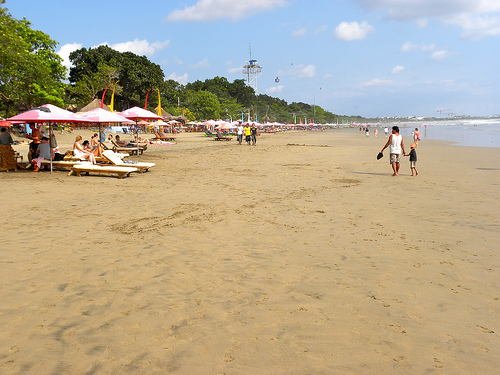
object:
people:
[236, 122, 259, 146]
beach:
[0, 129, 497, 375]